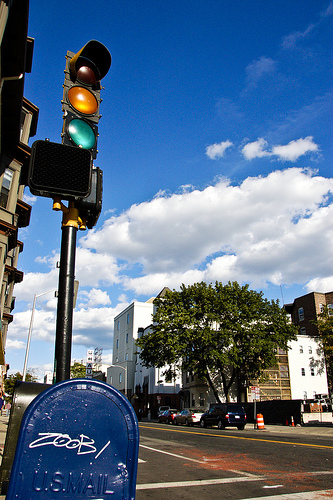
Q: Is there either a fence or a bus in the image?
A: No, there are no fences or buses.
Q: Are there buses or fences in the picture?
A: No, there are no fences or buses.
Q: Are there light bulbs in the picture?
A: No, there are no light bulbs.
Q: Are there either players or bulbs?
A: No, there are no bulbs or players.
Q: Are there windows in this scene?
A: Yes, there is a window.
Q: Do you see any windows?
A: Yes, there is a window.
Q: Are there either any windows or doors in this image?
A: Yes, there is a window.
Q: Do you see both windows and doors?
A: No, there is a window but no doors.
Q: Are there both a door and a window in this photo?
A: No, there is a window but no doors.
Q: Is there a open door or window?
A: Yes, there is an open window.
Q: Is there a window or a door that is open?
A: Yes, the window is open.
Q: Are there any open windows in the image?
A: Yes, there is an open window.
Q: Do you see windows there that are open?
A: Yes, there is a window that is open.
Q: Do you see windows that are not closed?
A: Yes, there is a open window.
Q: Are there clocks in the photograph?
A: No, there are no clocks.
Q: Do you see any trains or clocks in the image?
A: No, there are no clocks or trains.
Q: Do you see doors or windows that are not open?
A: No, there is a window but it is open.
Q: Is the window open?
A: Yes, the window is open.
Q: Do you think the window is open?
A: Yes, the window is open.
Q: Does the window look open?
A: Yes, the window is open.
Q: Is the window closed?
A: No, the window is open.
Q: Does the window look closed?
A: No, the window is open.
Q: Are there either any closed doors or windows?
A: No, there is a window but it is open.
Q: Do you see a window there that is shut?
A: No, there is a window but it is open.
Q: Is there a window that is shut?
A: No, there is a window but it is open.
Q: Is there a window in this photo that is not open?
A: No, there is a window but it is open.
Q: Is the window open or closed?
A: The window is open.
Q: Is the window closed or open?
A: The window is open.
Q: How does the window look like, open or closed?
A: The window is open.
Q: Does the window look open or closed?
A: The window is open.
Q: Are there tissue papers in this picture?
A: No, there are no tissue papers.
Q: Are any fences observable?
A: No, there are no fences.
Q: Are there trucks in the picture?
A: No, there are no trucks.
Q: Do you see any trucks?
A: No, there are no trucks.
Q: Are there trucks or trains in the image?
A: No, there are no trucks or trains.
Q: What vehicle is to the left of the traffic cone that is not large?
A: The vehicle is a car.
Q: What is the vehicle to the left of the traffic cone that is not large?
A: The vehicle is a car.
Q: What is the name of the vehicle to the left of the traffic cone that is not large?
A: The vehicle is a car.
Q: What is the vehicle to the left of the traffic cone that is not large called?
A: The vehicle is a car.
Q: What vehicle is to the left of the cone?
A: The vehicle is a car.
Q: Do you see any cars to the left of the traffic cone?
A: Yes, there is a car to the left of the traffic cone.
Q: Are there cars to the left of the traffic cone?
A: Yes, there is a car to the left of the traffic cone.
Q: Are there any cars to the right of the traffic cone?
A: No, the car is to the left of the traffic cone.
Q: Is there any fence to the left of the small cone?
A: No, there is a car to the left of the cone.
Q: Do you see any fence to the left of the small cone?
A: No, there is a car to the left of the cone.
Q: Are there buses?
A: No, there are no buses.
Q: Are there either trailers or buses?
A: No, there are no buses or trailers.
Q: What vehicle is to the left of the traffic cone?
A: The vehicle is a car.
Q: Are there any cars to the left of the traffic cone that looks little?
A: Yes, there is a car to the left of the cone.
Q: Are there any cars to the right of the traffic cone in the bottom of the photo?
A: No, the car is to the left of the traffic cone.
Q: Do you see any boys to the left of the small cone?
A: No, there is a car to the left of the cone.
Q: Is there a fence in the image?
A: No, there are no fences.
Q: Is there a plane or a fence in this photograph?
A: No, there are no fences or airplanes.